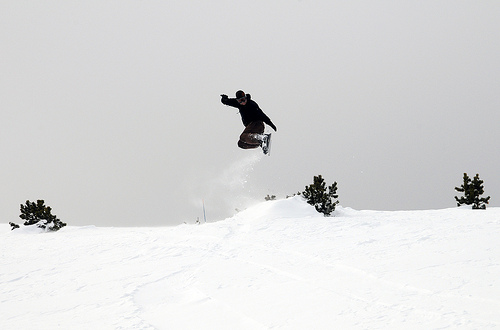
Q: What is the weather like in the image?
A: It is cloudy.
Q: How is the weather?
A: It is cloudy.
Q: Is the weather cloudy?
A: Yes, it is cloudy.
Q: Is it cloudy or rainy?
A: It is cloudy.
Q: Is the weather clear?
A: No, it is cloudy.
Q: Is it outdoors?
A: Yes, it is outdoors.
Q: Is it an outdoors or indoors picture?
A: It is outdoors.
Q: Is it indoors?
A: No, it is outdoors.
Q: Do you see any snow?
A: Yes, there is snow.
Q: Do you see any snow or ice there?
A: Yes, there is snow.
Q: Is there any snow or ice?
A: Yes, there is snow.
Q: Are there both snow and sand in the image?
A: No, there is snow but no sand.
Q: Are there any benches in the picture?
A: No, there are no benches.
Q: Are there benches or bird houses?
A: No, there are no benches or bird houses.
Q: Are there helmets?
A: No, there are no helmets.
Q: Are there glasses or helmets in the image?
A: No, there are no helmets or glasses.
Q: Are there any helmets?
A: No, there are no helmets.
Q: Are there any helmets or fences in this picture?
A: No, there are no helmets or fences.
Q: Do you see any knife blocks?
A: No, there are no knife blocks.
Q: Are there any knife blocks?
A: No, there are no knife blocks.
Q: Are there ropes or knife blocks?
A: No, there are no knife blocks or ropes.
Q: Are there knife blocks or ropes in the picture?
A: No, there are no knife blocks or ropes.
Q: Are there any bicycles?
A: No, there are no bicycles.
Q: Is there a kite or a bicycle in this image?
A: No, there are no bicycles or kites.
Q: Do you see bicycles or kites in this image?
A: No, there are no bicycles or kites.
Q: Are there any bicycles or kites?
A: No, there are no bicycles or kites.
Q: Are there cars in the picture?
A: No, there are no cars.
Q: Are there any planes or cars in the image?
A: No, there are no cars or planes.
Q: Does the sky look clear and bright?
A: No, the sky is bright but cloudy.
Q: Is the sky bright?
A: Yes, the sky is bright.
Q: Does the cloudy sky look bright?
A: Yes, the sky is bright.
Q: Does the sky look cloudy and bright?
A: Yes, the sky is cloudy and bright.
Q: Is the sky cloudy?
A: Yes, the sky is cloudy.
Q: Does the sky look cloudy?
A: Yes, the sky is cloudy.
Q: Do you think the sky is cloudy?
A: Yes, the sky is cloudy.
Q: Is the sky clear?
A: No, the sky is cloudy.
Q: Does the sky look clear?
A: No, the sky is cloudy.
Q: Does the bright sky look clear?
A: No, the sky is cloudy.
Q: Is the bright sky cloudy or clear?
A: The sky is cloudy.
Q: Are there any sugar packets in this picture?
A: No, there are no sugar packets.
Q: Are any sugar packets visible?
A: No, there are no sugar packets.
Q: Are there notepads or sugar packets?
A: No, there are no sugar packets or notepads.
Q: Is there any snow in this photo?
A: Yes, there is snow.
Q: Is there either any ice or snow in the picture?
A: Yes, there is snow.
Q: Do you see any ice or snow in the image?
A: Yes, there is snow.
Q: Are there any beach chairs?
A: No, there are no beach chairs.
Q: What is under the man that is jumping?
A: The snow is under the man.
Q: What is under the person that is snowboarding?
A: The snow is under the man.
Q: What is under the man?
A: The snow is under the man.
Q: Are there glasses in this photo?
A: No, there are no glasses.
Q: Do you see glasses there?
A: No, there are no glasses.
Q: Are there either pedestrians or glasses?
A: No, there are no glasses or pedestrians.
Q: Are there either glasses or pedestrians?
A: No, there are no glasses or pedestrians.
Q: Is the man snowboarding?
A: Yes, the man is snowboarding.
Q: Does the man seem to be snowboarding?
A: Yes, the man is snowboarding.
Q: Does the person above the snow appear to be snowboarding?
A: Yes, the man is snowboarding.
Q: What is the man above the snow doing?
A: The man is snowboarding.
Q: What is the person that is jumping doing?
A: The man is snowboarding.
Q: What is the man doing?
A: The man is snowboarding.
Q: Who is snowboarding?
A: The man is snowboarding.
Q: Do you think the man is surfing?
A: No, the man is snowboarding.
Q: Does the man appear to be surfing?
A: No, the man is snowboarding.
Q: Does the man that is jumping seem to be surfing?
A: No, the man is snowboarding.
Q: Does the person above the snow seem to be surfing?
A: No, the man is snowboarding.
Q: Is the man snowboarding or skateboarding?
A: The man is snowboarding.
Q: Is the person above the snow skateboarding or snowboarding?
A: The man is snowboarding.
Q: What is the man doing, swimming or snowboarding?
A: The man is snowboarding.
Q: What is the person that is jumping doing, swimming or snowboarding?
A: The man is snowboarding.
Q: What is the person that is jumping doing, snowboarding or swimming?
A: The man is snowboarding.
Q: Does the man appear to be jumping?
A: Yes, the man is jumping.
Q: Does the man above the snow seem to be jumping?
A: Yes, the man is jumping.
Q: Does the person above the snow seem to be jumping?
A: Yes, the man is jumping.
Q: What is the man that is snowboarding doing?
A: The man is jumping.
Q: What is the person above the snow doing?
A: The man is jumping.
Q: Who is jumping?
A: The man is jumping.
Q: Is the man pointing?
A: No, the man is jumping.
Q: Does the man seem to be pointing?
A: No, the man is jumping.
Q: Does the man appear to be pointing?
A: No, the man is jumping.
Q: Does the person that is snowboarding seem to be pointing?
A: No, the man is jumping.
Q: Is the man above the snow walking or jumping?
A: The man is jumping.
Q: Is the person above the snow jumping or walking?
A: The man is jumping.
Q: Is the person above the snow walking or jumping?
A: The man is jumping.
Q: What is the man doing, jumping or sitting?
A: The man is jumping.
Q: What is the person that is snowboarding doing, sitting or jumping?
A: The man is jumping.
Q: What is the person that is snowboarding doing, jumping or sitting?
A: The man is jumping.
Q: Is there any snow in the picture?
A: Yes, there is snow.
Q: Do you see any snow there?
A: Yes, there is snow.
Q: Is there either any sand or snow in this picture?
A: Yes, there is snow.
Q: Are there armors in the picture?
A: No, there are no armors.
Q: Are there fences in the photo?
A: No, there are no fences.